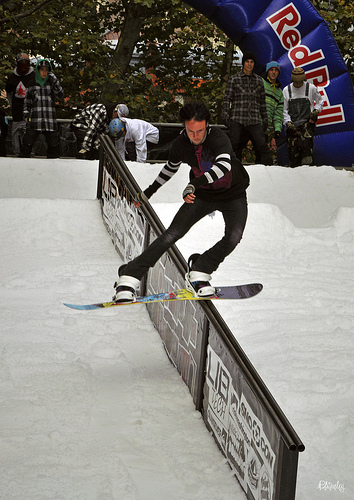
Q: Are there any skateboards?
A: No, there are no skateboards.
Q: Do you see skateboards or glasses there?
A: No, there are no skateboards or glasses.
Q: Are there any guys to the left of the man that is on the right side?
A: Yes, there is a guy to the left of the man.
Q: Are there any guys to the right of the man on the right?
A: No, the guy is to the left of the man.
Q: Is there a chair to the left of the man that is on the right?
A: No, there is a guy to the left of the man.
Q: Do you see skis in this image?
A: No, there are no skis.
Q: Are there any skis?
A: No, there are no skis.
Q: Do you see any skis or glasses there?
A: No, there are no skis or glasses.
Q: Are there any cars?
A: No, there are no cars.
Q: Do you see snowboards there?
A: Yes, there is a snowboard.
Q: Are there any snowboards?
A: Yes, there is a snowboard.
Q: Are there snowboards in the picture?
A: Yes, there is a snowboard.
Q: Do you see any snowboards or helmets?
A: Yes, there is a snowboard.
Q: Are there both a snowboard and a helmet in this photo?
A: Yes, there are both a snowboard and a helmet.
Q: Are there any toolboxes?
A: No, there are no toolboxes.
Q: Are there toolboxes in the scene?
A: No, there are no toolboxes.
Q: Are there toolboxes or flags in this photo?
A: No, there are no toolboxes or flags.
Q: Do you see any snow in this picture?
A: Yes, there is snow.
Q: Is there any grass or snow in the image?
A: Yes, there is snow.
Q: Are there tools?
A: No, there are no tools.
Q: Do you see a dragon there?
A: No, there are no dragons.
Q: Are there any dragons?
A: No, there are no dragons.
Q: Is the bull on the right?
A: Yes, the bull is on the right of the image.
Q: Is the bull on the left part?
A: No, the bull is on the right of the image.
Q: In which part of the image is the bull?
A: The bull is on the right of the image.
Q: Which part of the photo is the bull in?
A: The bull is on the right of the image.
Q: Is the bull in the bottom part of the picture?
A: No, the bull is in the top of the image.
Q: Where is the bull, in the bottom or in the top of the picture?
A: The bull is in the top of the image.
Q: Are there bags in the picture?
A: No, there are no bags.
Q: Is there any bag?
A: No, there are no bags.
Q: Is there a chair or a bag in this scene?
A: No, there are no bags or chairs.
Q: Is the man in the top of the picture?
A: Yes, the man is in the top of the image.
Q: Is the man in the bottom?
A: No, the man is in the top of the image.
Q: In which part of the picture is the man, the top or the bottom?
A: The man is in the top of the image.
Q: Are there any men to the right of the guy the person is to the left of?
A: Yes, there is a man to the right of the guy.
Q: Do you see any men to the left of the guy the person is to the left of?
A: No, the man is to the right of the guy.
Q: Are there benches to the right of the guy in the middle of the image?
A: No, there is a man to the right of the guy.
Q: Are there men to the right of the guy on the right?
A: Yes, there is a man to the right of the guy.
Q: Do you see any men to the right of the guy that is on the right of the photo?
A: Yes, there is a man to the right of the guy.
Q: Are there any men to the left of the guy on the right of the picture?
A: No, the man is to the right of the guy.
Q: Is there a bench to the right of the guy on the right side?
A: No, there is a man to the right of the guy.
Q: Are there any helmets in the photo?
A: Yes, there is a helmet.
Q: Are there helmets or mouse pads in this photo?
A: Yes, there is a helmet.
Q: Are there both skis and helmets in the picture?
A: No, there is a helmet but no skis.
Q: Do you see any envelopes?
A: No, there are no envelopes.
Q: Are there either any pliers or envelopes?
A: No, there are no envelopes or pliers.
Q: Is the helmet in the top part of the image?
A: Yes, the helmet is in the top of the image.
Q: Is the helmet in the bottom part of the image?
A: No, the helmet is in the top of the image.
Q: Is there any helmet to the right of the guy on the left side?
A: Yes, there is a helmet to the right of the guy.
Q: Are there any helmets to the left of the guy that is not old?
A: No, the helmet is to the right of the guy.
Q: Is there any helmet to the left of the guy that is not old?
A: No, the helmet is to the right of the guy.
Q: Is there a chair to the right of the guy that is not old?
A: No, there is a helmet to the right of the guy.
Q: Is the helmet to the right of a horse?
A: No, the helmet is to the right of a guy.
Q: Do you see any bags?
A: No, there are no bags.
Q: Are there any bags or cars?
A: No, there are no bags or cars.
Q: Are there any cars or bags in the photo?
A: No, there are no bags or cars.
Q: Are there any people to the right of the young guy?
A: Yes, there is a person to the right of the guy.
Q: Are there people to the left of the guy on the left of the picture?
A: No, the person is to the right of the guy.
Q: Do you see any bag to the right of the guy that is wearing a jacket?
A: No, there is a person to the right of the guy.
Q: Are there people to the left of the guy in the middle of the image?
A: Yes, there is a person to the left of the guy.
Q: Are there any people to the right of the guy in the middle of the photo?
A: No, the person is to the left of the guy.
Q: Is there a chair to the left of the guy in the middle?
A: No, there is a person to the left of the guy.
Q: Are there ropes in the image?
A: No, there are no ropes.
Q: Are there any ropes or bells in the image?
A: No, there are no ropes or bells.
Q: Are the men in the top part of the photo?
A: Yes, the men are in the top of the image.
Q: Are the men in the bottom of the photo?
A: No, the men are in the top of the image.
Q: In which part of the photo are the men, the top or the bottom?
A: The men are in the top of the image.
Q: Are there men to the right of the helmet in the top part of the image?
A: No, the men are to the left of the helmet.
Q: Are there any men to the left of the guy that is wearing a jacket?
A: Yes, there are men to the left of the guy.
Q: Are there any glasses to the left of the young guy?
A: No, there are men to the left of the guy.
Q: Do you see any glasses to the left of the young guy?
A: No, there are men to the left of the guy.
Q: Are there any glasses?
A: No, there are no glasses.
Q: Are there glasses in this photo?
A: No, there are no glasses.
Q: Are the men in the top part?
A: Yes, the men are in the top of the image.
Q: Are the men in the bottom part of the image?
A: No, the men are in the top of the image.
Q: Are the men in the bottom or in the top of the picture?
A: The men are in the top of the image.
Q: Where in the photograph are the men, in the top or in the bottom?
A: The men are in the top of the image.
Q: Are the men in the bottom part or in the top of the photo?
A: The men are in the top of the image.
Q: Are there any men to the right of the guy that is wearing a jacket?
A: Yes, there are men to the right of the guy.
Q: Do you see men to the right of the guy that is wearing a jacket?
A: Yes, there are men to the right of the guy.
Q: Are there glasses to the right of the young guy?
A: No, there are men to the right of the guy.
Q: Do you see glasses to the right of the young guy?
A: No, there are men to the right of the guy.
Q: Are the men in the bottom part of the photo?
A: No, the men are in the top of the image.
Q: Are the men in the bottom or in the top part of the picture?
A: The men are in the top of the image.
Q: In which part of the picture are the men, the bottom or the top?
A: The men are in the top of the image.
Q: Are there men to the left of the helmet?
A: Yes, there are men to the left of the helmet.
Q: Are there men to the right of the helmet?
A: No, the men are to the left of the helmet.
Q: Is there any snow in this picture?
A: Yes, there is snow.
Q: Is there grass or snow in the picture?
A: Yes, there is snow.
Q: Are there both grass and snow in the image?
A: No, there is snow but no grass.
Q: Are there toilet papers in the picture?
A: No, there are no toilet papers.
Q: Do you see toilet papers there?
A: No, there are no toilet papers.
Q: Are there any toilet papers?
A: No, there are no toilet papers.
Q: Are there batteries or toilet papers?
A: No, there are no toilet papers or batteries.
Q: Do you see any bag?
A: No, there are no bags.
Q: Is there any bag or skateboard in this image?
A: No, there are no bags or skateboards.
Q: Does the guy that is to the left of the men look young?
A: Yes, the guy is young.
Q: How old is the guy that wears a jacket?
A: The guy is young.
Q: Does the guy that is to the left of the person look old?
A: No, the guy is young.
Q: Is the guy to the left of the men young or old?
A: The guy is young.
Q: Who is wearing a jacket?
A: The guy is wearing a jacket.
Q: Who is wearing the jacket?
A: The guy is wearing a jacket.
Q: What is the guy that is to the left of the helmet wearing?
A: The guy is wearing a jacket.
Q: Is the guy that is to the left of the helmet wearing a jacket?
A: Yes, the guy is wearing a jacket.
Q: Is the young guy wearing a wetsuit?
A: No, the guy is wearing a jacket.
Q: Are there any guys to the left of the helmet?
A: Yes, there is a guy to the left of the helmet.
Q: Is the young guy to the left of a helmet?
A: Yes, the guy is to the left of a helmet.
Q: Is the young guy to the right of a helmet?
A: No, the guy is to the left of a helmet.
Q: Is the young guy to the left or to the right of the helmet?
A: The guy is to the left of the helmet.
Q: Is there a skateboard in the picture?
A: No, there are no skateboards.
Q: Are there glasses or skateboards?
A: No, there are no skateboards or glasses.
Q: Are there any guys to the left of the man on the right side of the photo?
A: Yes, there is a guy to the left of the man.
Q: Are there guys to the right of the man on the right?
A: No, the guy is to the left of the man.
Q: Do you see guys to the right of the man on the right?
A: No, the guy is to the left of the man.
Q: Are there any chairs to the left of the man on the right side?
A: No, there is a guy to the left of the man.